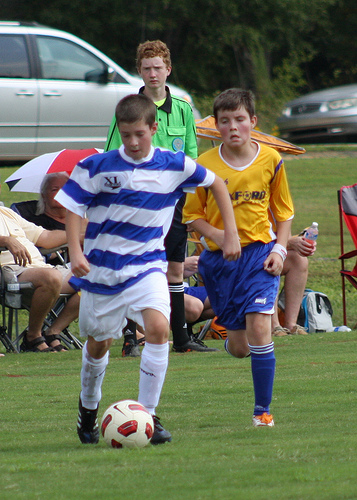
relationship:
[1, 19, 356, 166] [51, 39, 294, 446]
cars behind boys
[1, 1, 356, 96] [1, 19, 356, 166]
trees behind cars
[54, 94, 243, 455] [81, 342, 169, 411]
boy wearing shin guards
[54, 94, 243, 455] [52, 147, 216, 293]
boy wearing shirt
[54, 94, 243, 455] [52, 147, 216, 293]
boy wearing striped shirt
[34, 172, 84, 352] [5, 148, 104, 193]
woman holding umbrella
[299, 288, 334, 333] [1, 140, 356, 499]
bag sitting on grass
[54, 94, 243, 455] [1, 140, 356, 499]
boy running on grass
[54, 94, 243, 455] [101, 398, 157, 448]
boy kicking ball